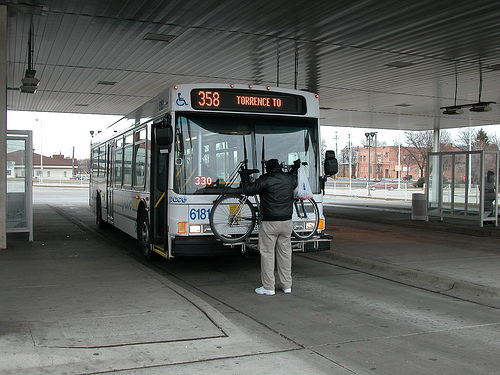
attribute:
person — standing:
[239, 159, 300, 295]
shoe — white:
[256, 286, 275, 296]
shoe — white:
[281, 286, 292, 292]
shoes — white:
[254, 285, 291, 295]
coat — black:
[240, 166, 298, 222]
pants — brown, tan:
[258, 220, 294, 291]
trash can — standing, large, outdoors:
[411, 193, 428, 220]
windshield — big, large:
[172, 110, 320, 195]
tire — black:
[137, 207, 162, 260]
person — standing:
[249, 159, 293, 294]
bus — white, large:
[91, 82, 330, 262]